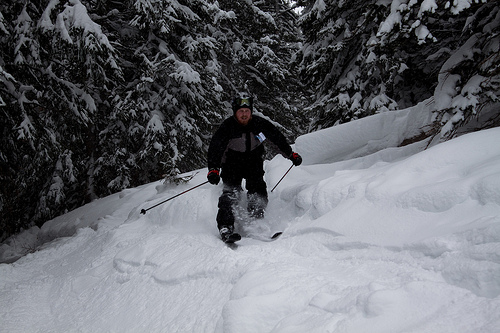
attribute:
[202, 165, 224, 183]
gloves — black and red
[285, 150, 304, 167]
gloves — black and red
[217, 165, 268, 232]
pants — black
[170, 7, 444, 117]
trees — snow covered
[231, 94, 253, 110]
hat — black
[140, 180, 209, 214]
pole — black 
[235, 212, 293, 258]
shadows — dark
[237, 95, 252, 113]
ski helmet — black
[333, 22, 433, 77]
trees — snow covered, pine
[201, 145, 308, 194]
gloves — black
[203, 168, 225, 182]
glove — black and red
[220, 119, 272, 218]
snowsuit — black, gray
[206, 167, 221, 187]
gloves — black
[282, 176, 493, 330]
snow — deep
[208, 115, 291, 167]
jacket — black, gray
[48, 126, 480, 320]
snow — white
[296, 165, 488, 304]
snow — is fluffy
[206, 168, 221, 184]
glove — red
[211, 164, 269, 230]
pants — black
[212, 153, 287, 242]
pants — black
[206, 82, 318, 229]
man — standing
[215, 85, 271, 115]
knit cap — winter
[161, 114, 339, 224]
jacket — black, brown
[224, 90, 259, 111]
helmet — black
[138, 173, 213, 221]
ski pole — black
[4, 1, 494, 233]
trees — filled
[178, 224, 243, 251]
ski — black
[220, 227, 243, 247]
ski — black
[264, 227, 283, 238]
ski — black